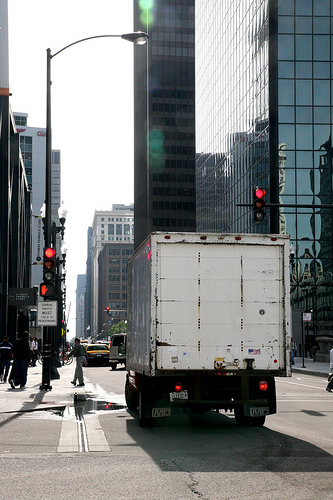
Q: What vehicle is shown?
A: A van.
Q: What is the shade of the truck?
A: White.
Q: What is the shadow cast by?
A: A vehicle.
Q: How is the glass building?
A: Tall.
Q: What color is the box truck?
A: White.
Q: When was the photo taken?
A: Daytime.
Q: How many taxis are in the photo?
A: One.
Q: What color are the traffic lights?
A: Red.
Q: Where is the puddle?
A: To the left of the box truck.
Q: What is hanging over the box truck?
A: A street light.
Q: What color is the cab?
A: Yellow.